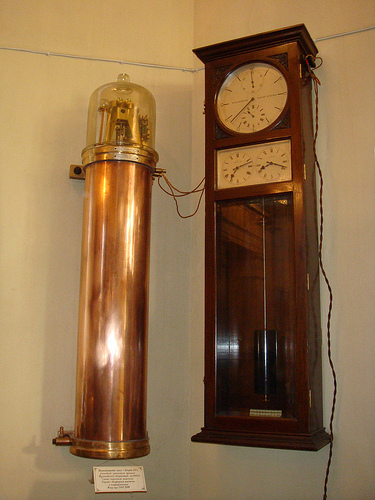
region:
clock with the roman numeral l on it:
[199, 123, 304, 200]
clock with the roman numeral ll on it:
[192, 128, 318, 217]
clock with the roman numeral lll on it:
[193, 131, 316, 211]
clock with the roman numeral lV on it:
[205, 115, 323, 208]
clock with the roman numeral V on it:
[189, 126, 320, 204]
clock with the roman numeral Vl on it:
[190, 120, 321, 212]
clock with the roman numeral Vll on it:
[181, 119, 324, 215]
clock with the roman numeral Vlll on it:
[178, 126, 313, 210]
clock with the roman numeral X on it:
[190, 127, 318, 197]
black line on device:
[247, 65, 257, 81]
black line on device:
[261, 65, 273, 79]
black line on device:
[273, 74, 282, 87]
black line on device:
[275, 87, 286, 97]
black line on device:
[262, 112, 272, 128]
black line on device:
[232, 118, 243, 132]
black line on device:
[221, 112, 233, 123]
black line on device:
[220, 100, 231, 108]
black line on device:
[224, 85, 234, 96]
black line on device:
[234, 71, 241, 82]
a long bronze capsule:
[65, 75, 180, 485]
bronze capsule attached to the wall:
[55, 71, 159, 481]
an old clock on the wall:
[185, 21, 346, 464]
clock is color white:
[214, 57, 292, 137]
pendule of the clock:
[248, 197, 282, 385]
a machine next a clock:
[64, 15, 343, 470]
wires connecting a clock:
[133, 131, 210, 227]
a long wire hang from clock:
[307, 56, 349, 498]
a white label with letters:
[91, 459, 149, 495]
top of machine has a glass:
[76, 69, 170, 175]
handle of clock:
[231, 91, 254, 122]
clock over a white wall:
[157, 9, 362, 486]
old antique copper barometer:
[41, 69, 158, 463]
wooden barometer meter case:
[184, 22, 336, 454]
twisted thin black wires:
[300, 53, 339, 498]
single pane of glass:
[210, 183, 298, 426]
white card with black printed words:
[83, 460, 147, 491]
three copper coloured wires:
[153, 159, 211, 220]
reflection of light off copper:
[85, 306, 132, 375]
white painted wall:
[0, 1, 373, 498]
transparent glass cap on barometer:
[69, 69, 171, 171]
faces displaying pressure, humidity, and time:
[203, 53, 298, 189]